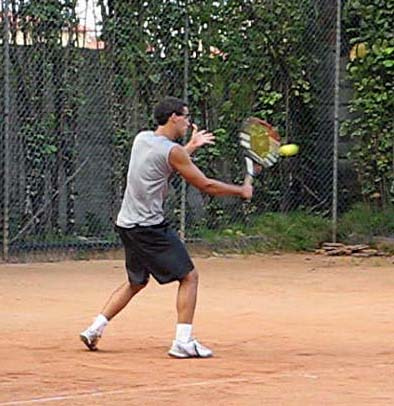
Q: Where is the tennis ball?
A: In the air.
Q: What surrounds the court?
A: Fence.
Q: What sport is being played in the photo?
A: Tennis.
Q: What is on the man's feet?
A: Sneakers.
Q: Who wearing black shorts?
A: A man.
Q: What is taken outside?
A: A Picture.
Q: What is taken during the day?
A: A Picture.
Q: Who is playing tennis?
A: A man.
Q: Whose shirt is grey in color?
A: The man's.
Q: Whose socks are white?
A: The man's.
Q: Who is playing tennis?
A: A man.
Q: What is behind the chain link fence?
A: Trees.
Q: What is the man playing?
A: Tennis.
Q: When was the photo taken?
A: Daytime.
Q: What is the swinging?
A: Tennis racket.